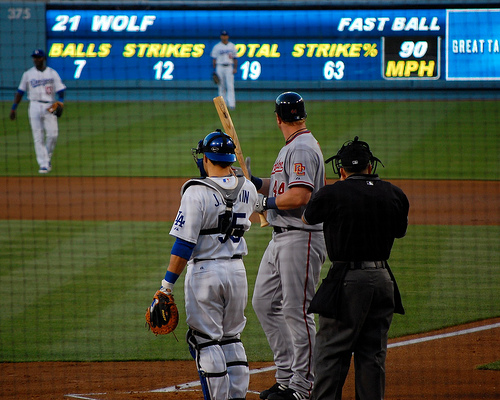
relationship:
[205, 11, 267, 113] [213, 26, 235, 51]
head of man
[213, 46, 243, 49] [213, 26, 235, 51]
neck of man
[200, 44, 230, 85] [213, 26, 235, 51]
arm of man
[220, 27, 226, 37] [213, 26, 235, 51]
ear of man